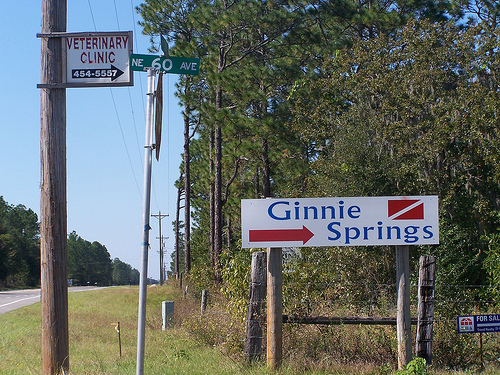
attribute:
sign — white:
[238, 188, 449, 269]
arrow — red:
[241, 226, 314, 247]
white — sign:
[227, 180, 447, 266]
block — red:
[384, 194, 431, 225]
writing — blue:
[271, 200, 361, 220]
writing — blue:
[325, 213, 436, 247]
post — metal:
[133, 71, 165, 356]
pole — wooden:
[32, 25, 80, 373]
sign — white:
[229, 189, 448, 256]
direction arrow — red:
[245, 224, 318, 242]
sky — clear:
[4, 14, 174, 264]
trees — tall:
[1, 194, 142, 297]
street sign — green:
[127, 46, 207, 85]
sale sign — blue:
[461, 310, 499, 340]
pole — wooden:
[259, 256, 293, 365]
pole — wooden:
[390, 256, 422, 363]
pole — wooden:
[33, 7, 82, 372]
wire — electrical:
[90, 14, 166, 241]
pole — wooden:
[390, 253, 415, 367]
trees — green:
[1, 191, 153, 296]